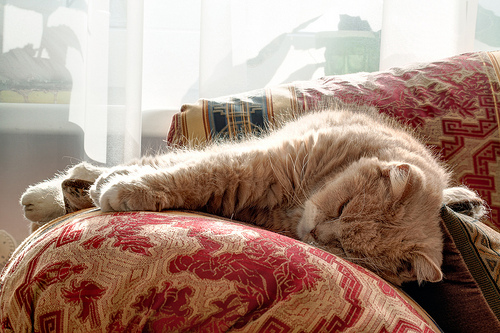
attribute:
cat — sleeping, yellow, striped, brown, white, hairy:
[70, 133, 452, 287]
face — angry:
[299, 187, 369, 261]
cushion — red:
[412, 66, 472, 103]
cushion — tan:
[372, 80, 394, 93]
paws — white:
[108, 189, 135, 210]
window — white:
[48, 18, 106, 61]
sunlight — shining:
[45, 43, 73, 94]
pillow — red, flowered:
[448, 224, 488, 316]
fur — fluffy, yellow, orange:
[314, 131, 341, 151]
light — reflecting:
[189, 28, 252, 54]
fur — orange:
[269, 150, 305, 202]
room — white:
[25, 8, 499, 68]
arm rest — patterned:
[176, 232, 254, 280]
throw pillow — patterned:
[450, 228, 468, 315]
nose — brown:
[312, 215, 331, 244]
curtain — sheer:
[66, 41, 126, 115]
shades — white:
[144, 42, 207, 58]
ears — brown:
[410, 161, 421, 195]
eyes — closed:
[334, 195, 354, 215]